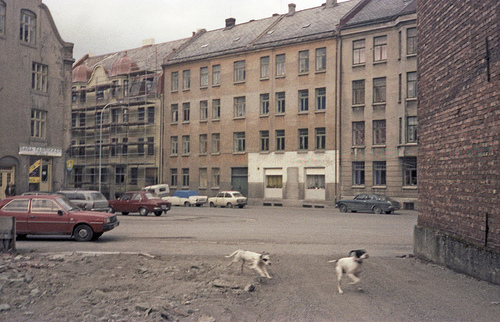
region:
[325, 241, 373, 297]
white dog with black face running in street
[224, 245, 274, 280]
white dog running with black eye in street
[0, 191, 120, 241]
red car parked in dusty street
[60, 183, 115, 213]
silver car parked in dusty street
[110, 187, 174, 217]
red car parked in dusty street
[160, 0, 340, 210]
brown attached building in center of street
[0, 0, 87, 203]
curved stone building beside cars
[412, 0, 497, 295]
red brick wall lining street next to dogs running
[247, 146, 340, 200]
white section of brown building with two garage doors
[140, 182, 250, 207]
three white cars parked on street one with blue top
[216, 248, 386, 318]
The dogs are running.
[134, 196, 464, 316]
The ground is dirt.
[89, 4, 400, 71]
The roof is gray.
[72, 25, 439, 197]
The building is large.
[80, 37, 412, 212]
Many windows are in the building.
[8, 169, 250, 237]
The cars are parked.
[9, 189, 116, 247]
The car is red.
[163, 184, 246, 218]
The cars are white.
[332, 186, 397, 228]
The car is next to the building.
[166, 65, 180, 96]
window on an old building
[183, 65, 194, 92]
window on an old building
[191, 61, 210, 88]
window on an old building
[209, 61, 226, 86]
window on an old building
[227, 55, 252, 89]
window on an old building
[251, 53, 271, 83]
window on an old building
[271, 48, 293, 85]
window on an old building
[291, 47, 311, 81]
window on an old building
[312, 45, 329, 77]
window on an old building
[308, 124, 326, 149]
window on an old building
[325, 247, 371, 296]
a dog running on a street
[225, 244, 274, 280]
a dog running on the street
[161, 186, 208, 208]
a white car with a blue tarp on top of it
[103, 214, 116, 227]
the headlight of a car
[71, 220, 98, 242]
the wheel of a car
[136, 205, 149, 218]
the wheel of a car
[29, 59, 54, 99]
the window of a building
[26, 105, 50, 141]
the window of a building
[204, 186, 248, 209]
a little white car parked on a street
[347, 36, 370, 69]
the window of a building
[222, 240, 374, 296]
dogs running in a street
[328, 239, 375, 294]
dog is black and white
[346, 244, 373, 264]
dog has black head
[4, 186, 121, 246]
red car parked on the side of the street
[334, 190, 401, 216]
black car parked on the side of the street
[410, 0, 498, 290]
brick building on the side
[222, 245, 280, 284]
a white dog is running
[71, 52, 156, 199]
scaffolding on side of building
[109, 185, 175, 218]
red car parked in the road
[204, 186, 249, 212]
small white car parked in road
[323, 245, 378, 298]
a dog that is being chased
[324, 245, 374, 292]
dog is black and white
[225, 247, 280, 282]
dog color is white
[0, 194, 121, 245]
car color is red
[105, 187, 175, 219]
car color is red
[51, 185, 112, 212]
car color is grey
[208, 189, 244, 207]
car color is white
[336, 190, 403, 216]
car color is black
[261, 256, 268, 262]
dog has a black eye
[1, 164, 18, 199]
man is standing in front of the door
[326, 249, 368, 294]
Running white dog with black face.